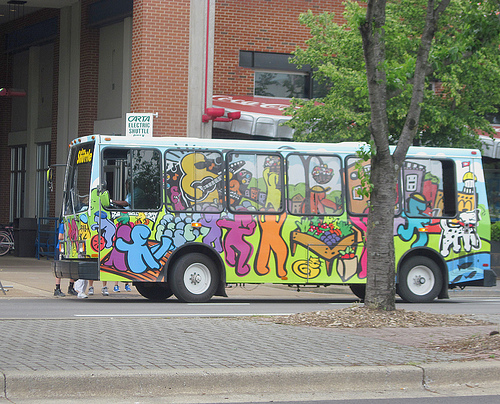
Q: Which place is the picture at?
A: It is at the road.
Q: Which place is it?
A: It is a road.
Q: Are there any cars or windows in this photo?
A: Yes, there is a window.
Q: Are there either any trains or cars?
A: No, there are no cars or trains.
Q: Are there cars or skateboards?
A: No, there are no cars or skateboards.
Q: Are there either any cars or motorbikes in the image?
A: No, there are no cars or motorbikes.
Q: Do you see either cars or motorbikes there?
A: No, there are no cars or motorbikes.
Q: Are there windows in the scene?
A: Yes, there is a window.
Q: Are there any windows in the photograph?
A: Yes, there is a window.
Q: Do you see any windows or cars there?
A: Yes, there is a window.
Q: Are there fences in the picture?
A: No, there are no fences.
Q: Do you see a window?
A: Yes, there is a window.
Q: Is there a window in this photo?
A: Yes, there is a window.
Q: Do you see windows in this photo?
A: Yes, there is a window.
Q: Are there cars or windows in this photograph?
A: Yes, there is a window.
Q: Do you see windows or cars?
A: Yes, there is a window.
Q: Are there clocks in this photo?
A: No, there are no clocks.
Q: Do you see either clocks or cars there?
A: No, there are no clocks or cars.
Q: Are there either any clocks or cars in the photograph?
A: No, there are no clocks or cars.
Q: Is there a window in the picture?
A: Yes, there is a window.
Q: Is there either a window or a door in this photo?
A: Yes, there is a window.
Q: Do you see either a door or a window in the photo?
A: Yes, there is a window.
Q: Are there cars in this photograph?
A: No, there are no cars.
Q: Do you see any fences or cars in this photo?
A: No, there are no cars or fences.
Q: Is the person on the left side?
A: Yes, the person is on the left of the image.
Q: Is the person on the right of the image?
A: No, the person is on the left of the image.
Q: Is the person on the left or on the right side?
A: The person is on the left of the image.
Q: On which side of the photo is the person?
A: The person is on the left of the image.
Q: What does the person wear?
A: The person wears shoes.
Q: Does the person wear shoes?
A: Yes, the person wears shoes.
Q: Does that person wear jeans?
A: No, the person wears shoes.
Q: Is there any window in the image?
A: Yes, there is a window.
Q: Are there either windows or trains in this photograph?
A: Yes, there is a window.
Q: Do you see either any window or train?
A: Yes, there is a window.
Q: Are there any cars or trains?
A: No, there are no cars or trains.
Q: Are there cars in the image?
A: No, there are no cars.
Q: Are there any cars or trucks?
A: No, there are no cars or trucks.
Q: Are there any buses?
A: Yes, there is a bus.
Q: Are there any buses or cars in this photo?
A: Yes, there is a bus.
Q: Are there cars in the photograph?
A: No, there are no cars.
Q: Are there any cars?
A: No, there are no cars.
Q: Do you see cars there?
A: No, there are no cars.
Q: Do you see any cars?
A: No, there are no cars.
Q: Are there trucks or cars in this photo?
A: No, there are no cars or trucks.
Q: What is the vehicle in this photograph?
A: The vehicle is a bus.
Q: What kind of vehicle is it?
A: The vehicle is a bus.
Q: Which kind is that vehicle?
A: That is a bus.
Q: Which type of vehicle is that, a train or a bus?
A: That is a bus.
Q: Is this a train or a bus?
A: This is a bus.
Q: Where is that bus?
A: The bus is on the road.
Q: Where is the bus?
A: The bus is on the road.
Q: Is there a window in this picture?
A: Yes, there is a window.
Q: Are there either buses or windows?
A: Yes, there is a window.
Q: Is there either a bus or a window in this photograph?
A: Yes, there is a window.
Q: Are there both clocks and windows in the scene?
A: No, there is a window but no clocks.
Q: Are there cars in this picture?
A: No, there are no cars.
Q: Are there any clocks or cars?
A: No, there are no cars or clocks.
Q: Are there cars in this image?
A: No, there are no cars.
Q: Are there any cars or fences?
A: No, there are no cars or fences.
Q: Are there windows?
A: Yes, there is a window.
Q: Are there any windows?
A: Yes, there is a window.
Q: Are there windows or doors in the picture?
A: Yes, there is a window.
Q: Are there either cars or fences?
A: No, there are no cars or fences.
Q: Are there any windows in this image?
A: Yes, there is a window.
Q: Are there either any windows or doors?
A: Yes, there is a window.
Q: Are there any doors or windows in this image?
A: Yes, there is a window.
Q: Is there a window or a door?
A: Yes, there is a window.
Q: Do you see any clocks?
A: No, there are no clocks.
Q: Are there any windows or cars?
A: Yes, there is a window.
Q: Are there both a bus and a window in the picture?
A: Yes, there are both a window and a bus.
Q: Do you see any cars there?
A: No, there are no cars.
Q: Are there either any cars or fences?
A: No, there are no cars or fences.